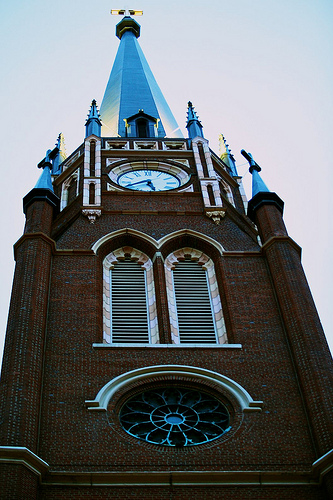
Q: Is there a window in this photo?
A: Yes, there is a window.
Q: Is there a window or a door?
A: Yes, there is a window.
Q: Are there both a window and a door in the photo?
A: No, there is a window but no doors.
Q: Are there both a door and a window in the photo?
A: No, there is a window but no doors.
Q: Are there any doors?
A: No, there are no doors.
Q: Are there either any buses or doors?
A: No, there are no doors or buses.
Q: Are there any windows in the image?
A: Yes, there is a window.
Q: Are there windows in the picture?
A: Yes, there is a window.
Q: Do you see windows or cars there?
A: Yes, there is a window.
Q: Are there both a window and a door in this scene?
A: No, there is a window but no doors.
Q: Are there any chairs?
A: No, there are no chairs.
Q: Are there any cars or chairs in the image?
A: No, there are no chairs or cars.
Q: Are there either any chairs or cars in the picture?
A: No, there are no chairs or cars.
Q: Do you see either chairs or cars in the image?
A: No, there are no chairs or cars.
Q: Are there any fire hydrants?
A: No, there are no fire hydrants.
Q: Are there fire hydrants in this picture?
A: No, there are no fire hydrants.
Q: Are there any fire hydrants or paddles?
A: No, there are no fire hydrants or paddles.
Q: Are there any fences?
A: No, there are no fences.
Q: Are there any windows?
A: Yes, there is a window.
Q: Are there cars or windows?
A: Yes, there is a window.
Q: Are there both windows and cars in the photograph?
A: No, there is a window but no cars.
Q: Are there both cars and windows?
A: No, there is a window but no cars.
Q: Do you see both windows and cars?
A: No, there is a window but no cars.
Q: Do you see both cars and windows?
A: No, there is a window but no cars.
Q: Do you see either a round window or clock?
A: Yes, there is a round window.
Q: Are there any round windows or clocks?
A: Yes, there is a round window.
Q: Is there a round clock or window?
A: Yes, there is a round window.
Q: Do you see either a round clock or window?
A: Yes, there is a round window.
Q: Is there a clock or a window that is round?
A: Yes, the window is round.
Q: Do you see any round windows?
A: Yes, there is a round window.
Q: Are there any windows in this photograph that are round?
A: Yes, there is a window that is round.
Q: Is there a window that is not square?
A: Yes, there is a round window.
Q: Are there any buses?
A: No, there are no buses.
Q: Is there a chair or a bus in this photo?
A: No, there are no buses or chairs.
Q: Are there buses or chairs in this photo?
A: No, there are no buses or chairs.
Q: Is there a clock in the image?
A: Yes, there is a clock.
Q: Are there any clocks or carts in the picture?
A: Yes, there is a clock.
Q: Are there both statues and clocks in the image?
A: No, there is a clock but no statues.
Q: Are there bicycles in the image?
A: No, there are no bicycles.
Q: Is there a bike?
A: No, there are no bikes.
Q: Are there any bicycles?
A: No, there are no bicycles.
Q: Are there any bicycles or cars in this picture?
A: No, there are no bicycles or cars.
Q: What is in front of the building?
A: The clock is in front of the building.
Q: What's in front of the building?
A: The clock is in front of the building.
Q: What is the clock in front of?
A: The clock is in front of the building.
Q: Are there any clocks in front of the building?
A: Yes, there is a clock in front of the building.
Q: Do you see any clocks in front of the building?
A: Yes, there is a clock in front of the building.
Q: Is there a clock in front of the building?
A: Yes, there is a clock in front of the building.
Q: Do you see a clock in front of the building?
A: Yes, there is a clock in front of the building.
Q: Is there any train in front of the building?
A: No, there is a clock in front of the building.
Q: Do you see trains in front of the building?
A: No, there is a clock in front of the building.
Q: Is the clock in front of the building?
A: Yes, the clock is in front of the building.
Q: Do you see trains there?
A: No, there are no trains.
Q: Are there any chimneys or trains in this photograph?
A: No, there are no trains or chimneys.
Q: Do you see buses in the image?
A: No, there are no buses.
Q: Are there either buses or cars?
A: No, there are no buses or cars.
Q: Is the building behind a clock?
A: Yes, the building is behind a clock.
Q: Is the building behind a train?
A: No, the building is behind a clock.